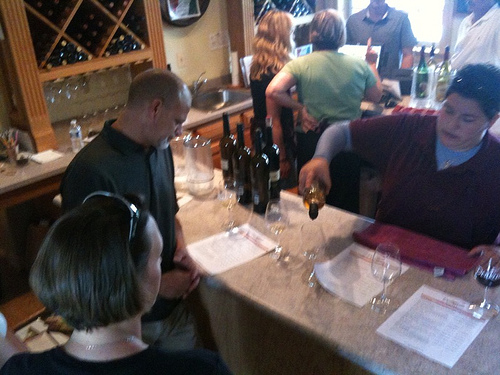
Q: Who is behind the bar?
A: The person in burgundy.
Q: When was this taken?
A: During the day.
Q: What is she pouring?
A: Wine.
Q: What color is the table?
A: Brown.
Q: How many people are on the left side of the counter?
A: Two.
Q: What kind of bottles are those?
A: Wine bottles.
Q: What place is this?
A: Bar.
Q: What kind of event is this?
A: Wine tasting.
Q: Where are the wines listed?
A: On the sheets of paper.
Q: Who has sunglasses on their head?
A: The woman at the bottom of the photo.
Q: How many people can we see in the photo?
A: 7.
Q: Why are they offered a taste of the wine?
A: So they can buy what they like.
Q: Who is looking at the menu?
A: The man on the left.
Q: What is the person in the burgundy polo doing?
A: Pouring wine.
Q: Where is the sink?
A: Against the wall.